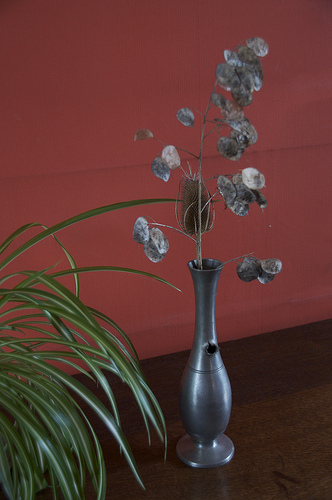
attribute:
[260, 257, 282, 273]
leaf — metallic  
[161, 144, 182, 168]
leaf — metallic  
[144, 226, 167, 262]
leaf — metallic  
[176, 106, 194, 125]
leaf — metallic  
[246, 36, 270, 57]
leaf — metallic  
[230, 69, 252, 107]
leaf — metallic  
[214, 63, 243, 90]
leaf — metallic  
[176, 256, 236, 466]
base — silver  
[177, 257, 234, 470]
vase — silver  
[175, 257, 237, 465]
vase — silver  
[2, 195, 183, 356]
leaves — long  , green  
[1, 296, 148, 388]
leaves — long  , green  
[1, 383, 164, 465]
leaves — long  , green  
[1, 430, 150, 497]
leaves — long  , green  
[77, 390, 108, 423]
stripe — white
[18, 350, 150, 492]
leaf — green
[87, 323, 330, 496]
table — brown, wood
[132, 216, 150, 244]
leaf — silver, round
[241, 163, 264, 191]
leaf — silver, round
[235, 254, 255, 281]
leaf — silver, round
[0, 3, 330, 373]
wall — pink, painted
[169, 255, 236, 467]
vase — silver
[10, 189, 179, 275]
leaf — green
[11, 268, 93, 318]
leaf — green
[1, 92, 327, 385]
wall — red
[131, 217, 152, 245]
flower — grey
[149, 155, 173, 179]
flower — grey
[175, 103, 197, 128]
flower — grey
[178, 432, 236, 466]
base — round